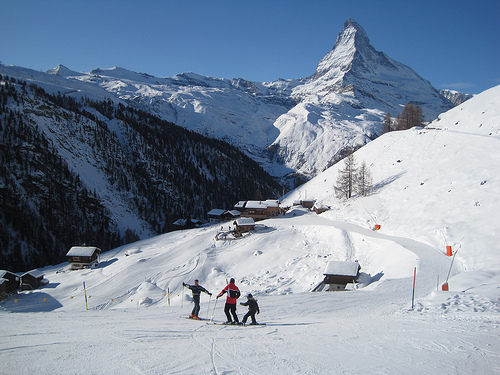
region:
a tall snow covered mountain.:
[290, 5, 454, 102]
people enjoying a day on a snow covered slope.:
[171, 257, 282, 334]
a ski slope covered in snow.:
[1, 88, 498, 305]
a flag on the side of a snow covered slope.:
[396, 257, 423, 319]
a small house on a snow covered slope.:
[49, 233, 117, 288]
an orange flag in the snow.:
[444, 239, 456, 262]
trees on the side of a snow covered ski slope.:
[0, 73, 285, 293]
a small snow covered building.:
[47, 237, 108, 269]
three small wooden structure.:
[216, 185, 290, 253]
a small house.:
[314, 248, 374, 299]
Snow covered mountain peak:
[316, 15, 429, 88]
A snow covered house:
[246, 198, 281, 219]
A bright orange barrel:
[446, 243, 453, 258]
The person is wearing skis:
[181, 276, 211, 321]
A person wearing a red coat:
[216, 276, 241, 325]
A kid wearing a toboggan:
[238, 291, 260, 326]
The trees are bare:
[338, 150, 371, 200]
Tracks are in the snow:
[23, 320, 499, 371]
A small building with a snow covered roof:
[66, 244, 101, 271]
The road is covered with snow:
[295, 205, 458, 330]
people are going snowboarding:
[164, 246, 274, 342]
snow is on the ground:
[285, 294, 370, 334]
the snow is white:
[286, 268, 434, 370]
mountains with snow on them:
[82, 31, 418, 208]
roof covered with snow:
[311, 249, 369, 294]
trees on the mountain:
[31, 103, 246, 209]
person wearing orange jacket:
[213, 277, 248, 322]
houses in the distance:
[204, 183, 311, 264]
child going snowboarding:
[234, 285, 271, 339]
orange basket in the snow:
[421, 233, 465, 275]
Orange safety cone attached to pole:
[444, 242, 454, 257]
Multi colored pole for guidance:
[409, 268, 417, 309]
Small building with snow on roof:
[64, 245, 101, 270]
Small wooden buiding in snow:
[323, 260, 360, 285]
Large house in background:
[231, 197, 283, 219]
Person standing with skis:
[179, 278, 214, 323]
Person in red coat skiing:
[213, 276, 241, 326]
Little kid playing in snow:
[240, 290, 263, 325]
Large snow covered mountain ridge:
[22, 66, 295, 107]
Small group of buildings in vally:
[1, 263, 44, 300]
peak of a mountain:
[332, 13, 374, 66]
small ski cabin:
[62, 236, 107, 274]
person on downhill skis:
[179, 274, 214, 324]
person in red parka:
[216, 276, 243, 326]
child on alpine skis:
[238, 290, 274, 332]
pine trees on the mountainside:
[332, 146, 379, 198]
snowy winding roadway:
[306, 208, 478, 301]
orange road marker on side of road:
[442, 242, 453, 257]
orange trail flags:
[7, 290, 92, 306]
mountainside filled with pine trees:
[7, 83, 204, 235]